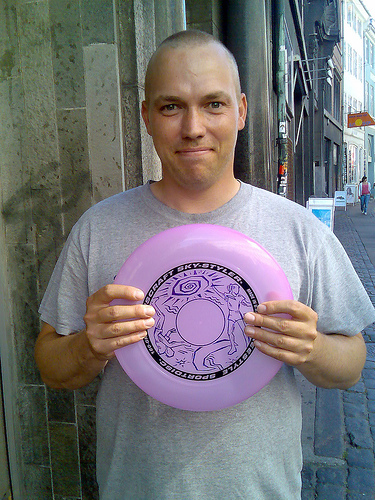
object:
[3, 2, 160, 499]
wall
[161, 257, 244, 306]
sky-styler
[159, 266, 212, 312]
sun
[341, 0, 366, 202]
buildings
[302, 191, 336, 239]
fridge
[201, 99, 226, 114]
eyes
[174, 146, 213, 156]
lips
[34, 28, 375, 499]
man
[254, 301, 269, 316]
nails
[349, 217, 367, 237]
ground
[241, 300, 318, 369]
hand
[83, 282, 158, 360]
hand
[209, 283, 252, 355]
woman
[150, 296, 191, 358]
woman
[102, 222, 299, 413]
frisbee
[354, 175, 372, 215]
woman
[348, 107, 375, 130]
sign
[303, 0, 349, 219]
building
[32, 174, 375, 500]
gray shirt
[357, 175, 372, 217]
person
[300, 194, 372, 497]
street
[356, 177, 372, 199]
jacket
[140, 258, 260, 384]
drawing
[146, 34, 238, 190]
face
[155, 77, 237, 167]
smile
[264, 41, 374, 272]
background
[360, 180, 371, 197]
shirt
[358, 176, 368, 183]
hair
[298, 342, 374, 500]
sidewalk